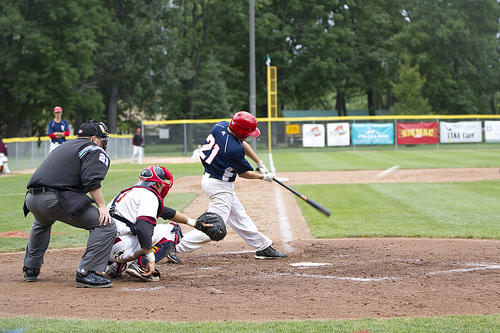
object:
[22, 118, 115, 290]
umpire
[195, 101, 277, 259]
batter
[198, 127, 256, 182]
blue jersey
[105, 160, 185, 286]
catcher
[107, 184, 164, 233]
white jersey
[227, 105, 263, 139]
helmet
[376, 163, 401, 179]
ball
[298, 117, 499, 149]
advertising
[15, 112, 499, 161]
fence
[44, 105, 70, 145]
third base coach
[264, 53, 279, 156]
foul pole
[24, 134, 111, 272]
uniform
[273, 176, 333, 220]
bat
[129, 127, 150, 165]
man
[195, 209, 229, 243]
catcher's mitt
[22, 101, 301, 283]
people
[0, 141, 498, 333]
baseball field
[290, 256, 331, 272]
home plate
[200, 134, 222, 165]
21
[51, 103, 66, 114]
baseball hat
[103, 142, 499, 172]
left field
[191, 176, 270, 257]
pants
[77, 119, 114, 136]
hat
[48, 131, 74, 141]
arms